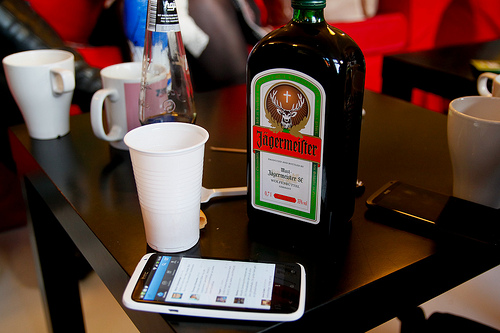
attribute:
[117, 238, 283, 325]
phone — off